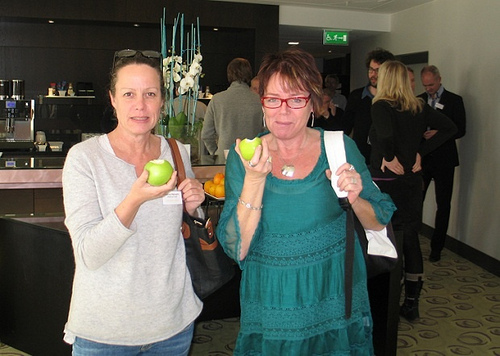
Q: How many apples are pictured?
A: Two.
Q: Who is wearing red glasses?
A: Woman on right.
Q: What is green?
A: Apples.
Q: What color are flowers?
A: White.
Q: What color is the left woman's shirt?
A: White.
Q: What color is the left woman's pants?
A: Blue.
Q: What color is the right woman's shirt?
A: Green.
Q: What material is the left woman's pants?
A: Denim.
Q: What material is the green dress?
A: Fabric.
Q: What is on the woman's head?
A: Sunglasses.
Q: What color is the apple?
A: Green.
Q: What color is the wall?
A: White.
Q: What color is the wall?
A: White.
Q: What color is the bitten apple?
A: Green.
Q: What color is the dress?
A: Green.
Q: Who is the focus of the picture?
A: Two women.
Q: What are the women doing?
A: Eating apples.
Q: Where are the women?
A: In a kitchen.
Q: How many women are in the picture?
A: Three.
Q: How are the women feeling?
A: Happy.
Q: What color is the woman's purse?
A: Black.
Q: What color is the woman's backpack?
A: White.